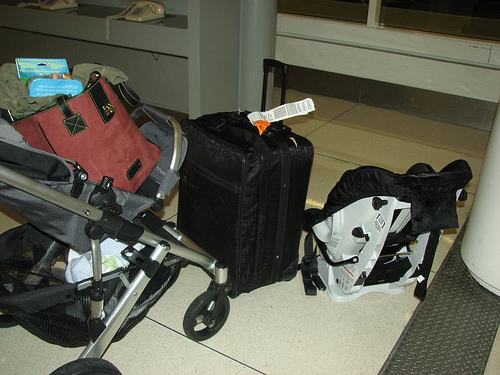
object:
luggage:
[173, 107, 317, 299]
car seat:
[299, 157, 471, 302]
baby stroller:
[0, 57, 232, 373]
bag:
[9, 71, 163, 197]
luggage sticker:
[246, 95, 318, 127]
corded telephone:
[104, 1, 168, 42]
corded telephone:
[13, 0, 78, 12]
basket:
[0, 223, 182, 349]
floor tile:
[265, 78, 358, 123]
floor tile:
[325, 102, 492, 160]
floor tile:
[303, 143, 486, 196]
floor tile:
[305, 149, 364, 209]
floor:
[0, 116, 495, 374]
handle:
[261, 56, 292, 133]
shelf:
[0, 0, 188, 37]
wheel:
[182, 288, 230, 342]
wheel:
[42, 355, 125, 373]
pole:
[235, 0, 280, 114]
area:
[1, 56, 475, 374]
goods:
[0, 57, 85, 101]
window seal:
[272, 9, 499, 52]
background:
[257, 0, 499, 133]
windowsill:
[271, 9, 499, 68]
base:
[269, 31, 499, 106]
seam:
[331, 124, 475, 154]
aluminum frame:
[1, 119, 228, 358]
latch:
[102, 103, 116, 117]